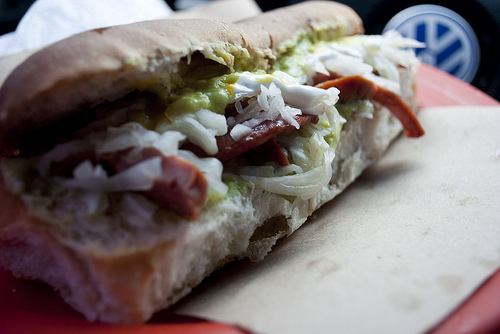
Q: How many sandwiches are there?
A: One.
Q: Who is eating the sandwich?
A: No one.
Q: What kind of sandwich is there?
A: Vegetable.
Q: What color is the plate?
A: Red.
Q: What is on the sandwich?
A: Onions.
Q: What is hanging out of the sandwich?
A: Peppers.